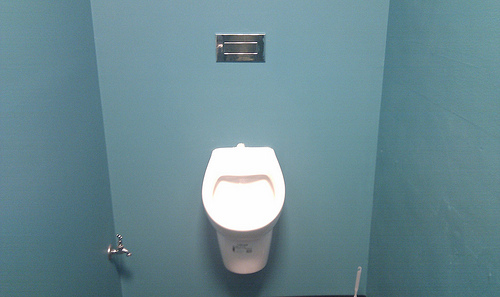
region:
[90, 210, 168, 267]
silver faucet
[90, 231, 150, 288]
silver faucet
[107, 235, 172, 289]
silver faucet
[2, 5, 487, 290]
A photograph of the inside of a men's bathroom.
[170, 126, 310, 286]
The urinal is white.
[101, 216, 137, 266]
A metal spigot on the wall.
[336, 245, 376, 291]
A toilet brush handle.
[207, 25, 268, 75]
A metal object on the wall.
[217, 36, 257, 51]
A rectangle shape on the metal object.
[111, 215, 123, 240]
A knob on the spigot.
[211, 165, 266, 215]
The bowl of the urinal.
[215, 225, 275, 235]
A shadow on the bottom of the urinal.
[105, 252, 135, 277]
A shadow under the spigot.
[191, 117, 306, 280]
urinal on the wall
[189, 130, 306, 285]
white porcelain urinal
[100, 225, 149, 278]
a faucet sticking out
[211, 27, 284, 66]
a silver box on the wall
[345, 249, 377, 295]
a white handle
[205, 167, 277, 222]
white bowl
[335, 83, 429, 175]
blue corner in a bathroom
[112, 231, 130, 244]
handle for the spout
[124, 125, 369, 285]
urinal attached to a blue wall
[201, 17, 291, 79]
stainless steel square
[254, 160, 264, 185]
the toilet is white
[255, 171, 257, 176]
the toilet is white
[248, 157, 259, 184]
the toilet is white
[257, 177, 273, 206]
the toilet is white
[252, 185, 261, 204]
the toilet is white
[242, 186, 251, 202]
the toilet is white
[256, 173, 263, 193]
the toilet is white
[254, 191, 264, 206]
the toilet is white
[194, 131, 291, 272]
Totlet on the wall.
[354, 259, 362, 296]
The handle of a brush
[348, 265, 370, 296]
A brush on the floor.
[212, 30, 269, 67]
A silver wall mount.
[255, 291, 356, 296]
Balck trim on the floor.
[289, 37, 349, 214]
A teal wall.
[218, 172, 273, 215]
The bowl of the tank.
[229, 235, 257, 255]
The logo on the toilet.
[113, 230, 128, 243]
The knob for the faucet.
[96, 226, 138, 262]
A silver water faucet.